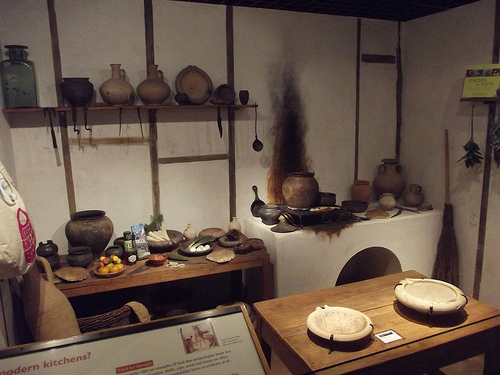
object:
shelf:
[2, 104, 257, 114]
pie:
[393, 277, 465, 317]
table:
[251, 269, 500, 375]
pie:
[306, 304, 372, 343]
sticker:
[373, 328, 403, 345]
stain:
[267, 45, 312, 205]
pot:
[282, 169, 319, 210]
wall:
[0, 0, 499, 308]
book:
[455, 65, 499, 103]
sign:
[1, 312, 267, 374]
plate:
[93, 264, 127, 278]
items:
[102, 258, 109, 264]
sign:
[463, 60, 500, 101]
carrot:
[144, 222, 165, 241]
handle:
[251, 185, 260, 200]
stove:
[272, 202, 369, 229]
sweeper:
[431, 130, 462, 291]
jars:
[135, 63, 170, 107]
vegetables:
[98, 266, 109, 273]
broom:
[430, 203, 458, 289]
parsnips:
[157, 214, 164, 226]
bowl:
[147, 230, 183, 252]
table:
[21, 230, 275, 301]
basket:
[67, 296, 141, 333]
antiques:
[97, 63, 136, 107]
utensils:
[251, 102, 264, 153]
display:
[0, 0, 500, 374]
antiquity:
[64, 209, 114, 258]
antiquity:
[228, 216, 241, 232]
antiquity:
[59, 77, 94, 107]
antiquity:
[66, 246, 94, 269]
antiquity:
[0, 44, 39, 108]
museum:
[0, 0, 499, 375]